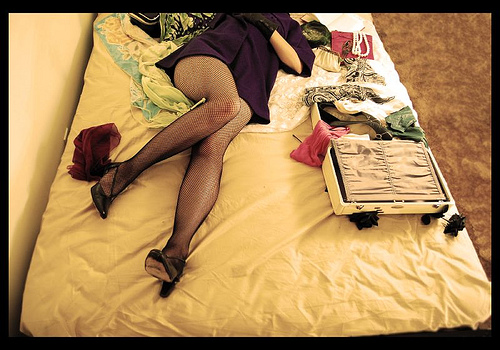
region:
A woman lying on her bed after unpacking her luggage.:
[49, 12, 487, 309]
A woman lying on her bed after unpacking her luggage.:
[62, 12, 482, 332]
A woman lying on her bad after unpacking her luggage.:
[64, 8, 481, 319]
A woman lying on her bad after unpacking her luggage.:
[72, 10, 477, 312]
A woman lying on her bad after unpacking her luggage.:
[57, 10, 472, 309]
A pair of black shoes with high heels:
[88, 162, 186, 298]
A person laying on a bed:
[21, 12, 491, 337]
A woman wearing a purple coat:
[88, 12, 315, 299]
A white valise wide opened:
[308, 98, 452, 215]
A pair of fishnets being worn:
[98, 53, 255, 261]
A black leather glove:
[231, 11, 276, 38]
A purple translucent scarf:
[66, 123, 121, 181]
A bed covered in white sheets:
[23, 14, 491, 338]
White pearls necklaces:
[351, 33, 368, 57]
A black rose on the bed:
[420, 212, 465, 237]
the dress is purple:
[192, 19, 318, 116]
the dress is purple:
[157, 13, 324, 155]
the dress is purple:
[154, 10, 314, 144]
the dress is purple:
[161, 17, 316, 136]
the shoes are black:
[82, 151, 201, 326]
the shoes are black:
[80, 153, 187, 299]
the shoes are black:
[73, 147, 204, 295]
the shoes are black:
[76, 159, 191, 311]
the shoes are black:
[87, 154, 190, 317]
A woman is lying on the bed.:
[90, 10, 314, 297]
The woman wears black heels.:
[146, 248, 184, 298]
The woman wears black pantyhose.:
[183, 160, 220, 208]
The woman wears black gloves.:
[240, 13, 274, 33]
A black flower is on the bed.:
[438, 213, 467, 235]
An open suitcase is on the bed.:
[320, 140, 452, 216]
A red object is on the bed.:
[73, 123, 120, 158]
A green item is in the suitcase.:
[394, 125, 421, 136]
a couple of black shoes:
[92, 160, 185, 298]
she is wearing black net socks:
[117, 61, 247, 251]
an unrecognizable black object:
[440, 211, 463, 234]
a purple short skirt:
[164, 11, 313, 122]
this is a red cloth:
[68, 123, 120, 180]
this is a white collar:
[353, 27, 369, 55]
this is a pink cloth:
[289, 122, 347, 165]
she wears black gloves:
[241, 13, 276, 37]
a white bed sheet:
[204, 242, 456, 319]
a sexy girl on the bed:
[91, 7, 316, 297]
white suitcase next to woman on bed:
[310, 67, 457, 232]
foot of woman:
[146, 244, 193, 299]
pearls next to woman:
[346, 24, 370, 62]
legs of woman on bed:
[91, 53, 257, 286]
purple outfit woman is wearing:
[163, 9, 320, 128]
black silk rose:
[418, 208, 470, 237]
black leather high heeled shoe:
[88, 156, 119, 219]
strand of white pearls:
[350, 26, 367, 57]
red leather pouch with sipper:
[332, 30, 374, 58]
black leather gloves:
[235, 10, 279, 40]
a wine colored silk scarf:
[66, 123, 122, 183]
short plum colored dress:
[154, 11, 311, 122]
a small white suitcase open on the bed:
[311, 92, 451, 217]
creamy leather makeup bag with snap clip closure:
[310, 42, 338, 72]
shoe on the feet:
[76, 163, 155, 233]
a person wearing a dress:
[146, 13, 343, 167]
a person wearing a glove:
[238, 14, 289, 39]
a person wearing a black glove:
[237, 10, 282, 45]